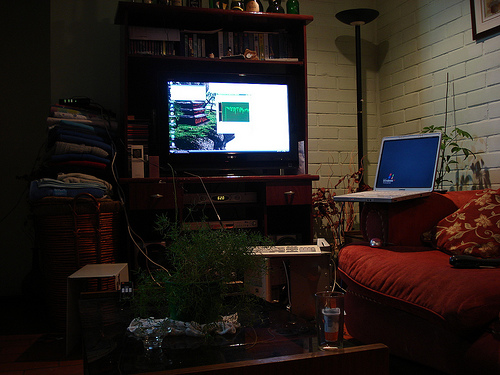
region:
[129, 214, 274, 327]
green potted plant on the table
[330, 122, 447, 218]
blue screensaver display on laptop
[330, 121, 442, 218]
laptop on red couch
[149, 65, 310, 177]
screen displaying computer desktop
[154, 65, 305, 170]
large screen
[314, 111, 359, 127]
white brick wall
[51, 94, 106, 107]
black electronic box with lights lit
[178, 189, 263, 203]
silver electronic box displaying the time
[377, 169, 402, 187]
Windows logo on blue display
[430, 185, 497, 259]
red and gold floral throw pillow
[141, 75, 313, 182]
A FLAT SCREEN TV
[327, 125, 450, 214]
A LAPTOP ON THE SOFA ARM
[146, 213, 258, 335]
A PLANT IN THE CENTER OF THE TABLE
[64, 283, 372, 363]
A COFFEE TABLE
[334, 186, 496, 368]
A RED SOFA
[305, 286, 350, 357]
AN EMPTY GLASS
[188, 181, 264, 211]
A CABLE BOX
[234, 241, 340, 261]
A COMPUTER KEYBOARD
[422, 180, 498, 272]
A RED AND GOLD SOFA PILLOW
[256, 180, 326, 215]
AN ENTERTAINMENT CENTER DRAWER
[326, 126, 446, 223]
a laptop sitting on a stand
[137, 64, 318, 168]
a television on a shelf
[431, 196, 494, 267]
a floral pillow on a red sofa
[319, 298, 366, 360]
a cup on a coffee table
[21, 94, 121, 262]
clothes stacked in a basket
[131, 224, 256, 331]
a plant on a table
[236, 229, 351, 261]
a white keyboard on a box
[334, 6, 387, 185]
a metal lamp in a corner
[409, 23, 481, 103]
a white brick wall behind a sofa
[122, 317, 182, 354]
a glass candy dish sitting on a table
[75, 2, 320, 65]
there are a few books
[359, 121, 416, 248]
there is a laptop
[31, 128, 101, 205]
there are a pile of clothes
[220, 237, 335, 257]
there is a keyboard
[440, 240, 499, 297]
there is a remote control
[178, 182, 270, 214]
there is a cable box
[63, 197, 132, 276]
there is a wicker basket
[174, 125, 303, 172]
the tv is on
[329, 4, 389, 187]
the light is off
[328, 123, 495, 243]
silver laptop on couch arm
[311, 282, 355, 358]
a glass water glass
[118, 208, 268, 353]
a house plant in a green pot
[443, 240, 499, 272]
the tv remote control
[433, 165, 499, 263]
a red and gold throw pillow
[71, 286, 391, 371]
a wood and glass table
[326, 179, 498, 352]
a red couch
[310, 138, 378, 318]
a tall red house plant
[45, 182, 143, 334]
a tall wicker basket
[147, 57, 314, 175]
a flat screen tv